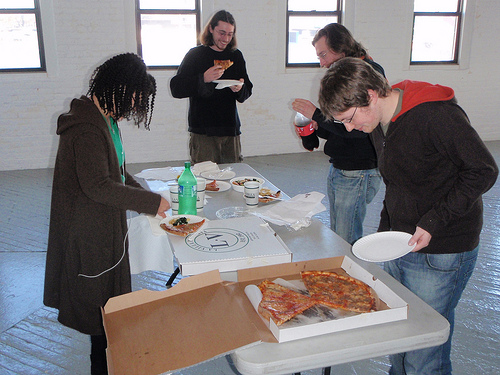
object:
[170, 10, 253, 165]
man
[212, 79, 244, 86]
plate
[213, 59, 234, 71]
pizza slice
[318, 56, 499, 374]
man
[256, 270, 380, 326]
pizza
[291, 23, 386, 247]
man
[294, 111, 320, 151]
cola bottle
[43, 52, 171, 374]
woman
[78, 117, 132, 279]
earphones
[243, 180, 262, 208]
cup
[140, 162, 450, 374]
table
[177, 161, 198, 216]
bottle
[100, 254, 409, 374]
box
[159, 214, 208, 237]
plate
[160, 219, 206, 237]
pizza slice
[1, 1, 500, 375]
room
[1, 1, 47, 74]
window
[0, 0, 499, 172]
wall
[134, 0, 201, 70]
window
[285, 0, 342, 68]
window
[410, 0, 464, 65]
window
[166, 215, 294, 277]
box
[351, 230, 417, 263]
plate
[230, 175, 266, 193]
bowl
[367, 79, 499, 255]
hoodie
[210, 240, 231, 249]
letter l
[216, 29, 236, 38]
glasses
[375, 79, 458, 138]
hood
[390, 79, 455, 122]
lining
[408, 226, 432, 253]
left hand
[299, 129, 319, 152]
cola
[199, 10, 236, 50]
hair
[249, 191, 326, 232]
napkins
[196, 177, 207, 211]
cup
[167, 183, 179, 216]
cup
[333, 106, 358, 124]
glasses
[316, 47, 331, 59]
glasses